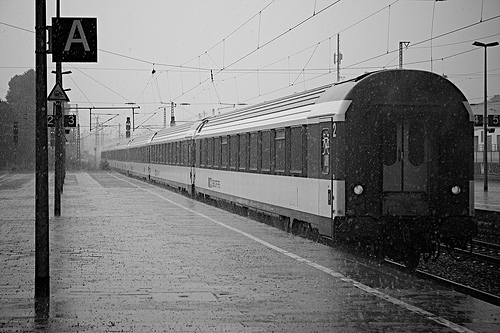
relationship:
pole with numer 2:
[45, 86, 60, 216] [43, 114, 57, 128]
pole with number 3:
[57, 99, 64, 220] [66, 116, 79, 127]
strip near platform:
[95, 164, 459, 333] [109, 92, 499, 289]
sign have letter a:
[41, 14, 99, 75] [53, 20, 99, 60]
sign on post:
[41, 14, 99, 75] [24, 1, 53, 333]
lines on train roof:
[102, 77, 337, 152] [92, 66, 481, 154]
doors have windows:
[376, 110, 432, 201] [384, 121, 427, 164]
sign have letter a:
[49, 14, 99, 67] [41, 14, 99, 75]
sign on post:
[49, 14, 99, 67] [24, 1, 53, 333]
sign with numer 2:
[45, 114, 59, 130] [43, 114, 57, 128]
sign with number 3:
[62, 111, 78, 128] [66, 116, 79, 127]